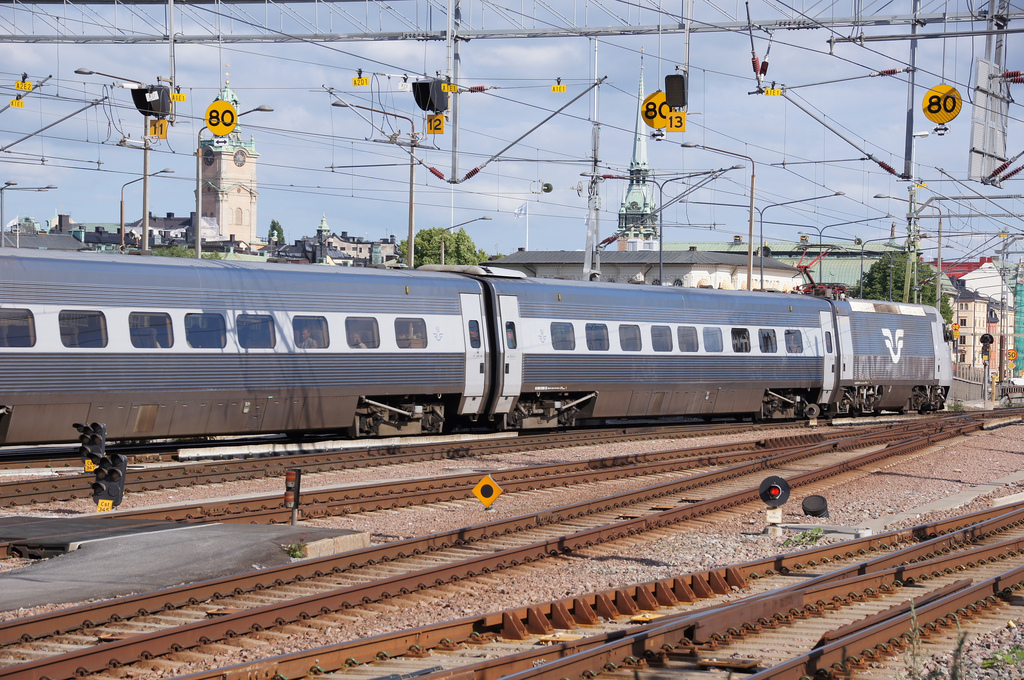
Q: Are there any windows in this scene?
A: Yes, there is a window.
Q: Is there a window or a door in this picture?
A: Yes, there is a window.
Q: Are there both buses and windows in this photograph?
A: No, there is a window but no buses.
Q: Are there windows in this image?
A: Yes, there is a window.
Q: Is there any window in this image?
A: Yes, there is a window.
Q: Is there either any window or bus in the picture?
A: Yes, there is a window.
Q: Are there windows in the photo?
A: Yes, there is a window.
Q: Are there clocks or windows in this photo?
A: Yes, there is a window.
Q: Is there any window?
A: Yes, there is a window.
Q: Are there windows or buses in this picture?
A: Yes, there is a window.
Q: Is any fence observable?
A: No, there are no fences.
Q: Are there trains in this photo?
A: Yes, there is a train.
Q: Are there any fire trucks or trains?
A: Yes, there is a train.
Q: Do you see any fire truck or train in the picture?
A: Yes, there is a train.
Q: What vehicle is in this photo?
A: The vehicle is a train.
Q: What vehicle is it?
A: The vehicle is a train.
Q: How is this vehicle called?
A: This is a train.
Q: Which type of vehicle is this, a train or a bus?
A: This is a train.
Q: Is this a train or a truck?
A: This is a train.